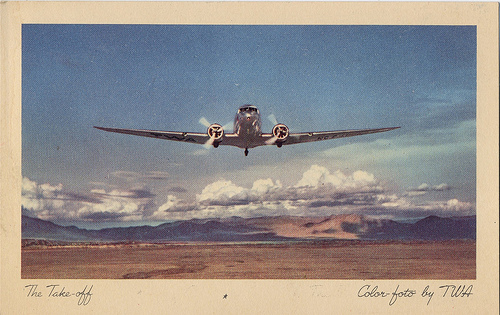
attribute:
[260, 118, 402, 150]
wing — silver, plane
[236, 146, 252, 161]
wheel — landing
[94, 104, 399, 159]
plane — silver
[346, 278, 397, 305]
word — black, cursive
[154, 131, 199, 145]
wing — black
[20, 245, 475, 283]
land — brown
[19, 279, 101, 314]
writing — cursive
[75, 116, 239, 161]
wing — silver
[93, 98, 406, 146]
plane — silver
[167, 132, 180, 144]
'w' — large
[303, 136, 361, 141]
writing — smaller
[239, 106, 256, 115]
windshield — black 